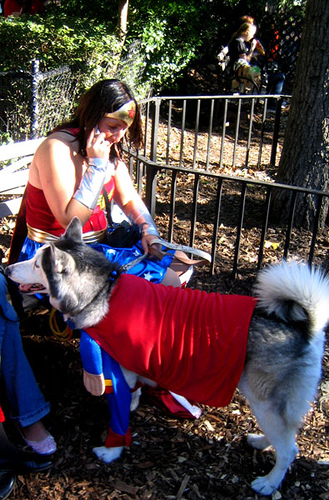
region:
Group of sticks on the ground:
[146, 445, 188, 476]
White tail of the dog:
[270, 268, 309, 294]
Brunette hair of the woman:
[95, 89, 110, 104]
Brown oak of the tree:
[281, 147, 326, 180]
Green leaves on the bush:
[143, 23, 167, 41]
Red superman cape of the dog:
[125, 308, 168, 337]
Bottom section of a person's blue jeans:
[19, 377, 34, 406]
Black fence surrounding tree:
[218, 175, 246, 276]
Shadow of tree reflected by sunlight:
[185, 202, 241, 225]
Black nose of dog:
[3, 266, 14, 276]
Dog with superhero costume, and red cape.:
[3, 217, 327, 498]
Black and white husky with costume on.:
[3, 214, 327, 497]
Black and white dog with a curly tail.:
[3, 213, 326, 498]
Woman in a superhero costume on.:
[5, 75, 204, 281]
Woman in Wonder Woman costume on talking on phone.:
[6, 74, 197, 288]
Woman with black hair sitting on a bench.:
[0, 75, 219, 285]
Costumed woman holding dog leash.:
[4, 73, 327, 493]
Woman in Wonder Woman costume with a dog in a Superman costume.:
[5, 78, 327, 495]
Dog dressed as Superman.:
[4, 213, 327, 497]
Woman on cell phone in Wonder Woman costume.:
[8, 73, 214, 286]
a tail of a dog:
[248, 258, 327, 337]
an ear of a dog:
[44, 238, 79, 280]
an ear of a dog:
[58, 214, 89, 245]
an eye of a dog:
[30, 255, 44, 274]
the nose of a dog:
[0, 264, 15, 280]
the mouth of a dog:
[11, 277, 47, 298]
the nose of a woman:
[108, 128, 123, 145]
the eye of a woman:
[105, 120, 118, 132]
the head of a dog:
[3, 212, 93, 315]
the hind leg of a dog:
[239, 359, 299, 494]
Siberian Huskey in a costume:
[2, 219, 314, 449]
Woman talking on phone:
[66, 75, 145, 165]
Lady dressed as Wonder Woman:
[11, 80, 167, 238]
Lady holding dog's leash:
[106, 234, 223, 285]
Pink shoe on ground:
[18, 423, 63, 456]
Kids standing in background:
[219, 12, 263, 71]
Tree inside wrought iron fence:
[276, 97, 328, 243]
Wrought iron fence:
[158, 89, 281, 180]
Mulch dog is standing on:
[191, 427, 316, 493]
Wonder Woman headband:
[102, 99, 137, 128]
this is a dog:
[109, 335, 225, 451]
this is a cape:
[154, 373, 220, 437]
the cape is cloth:
[180, 369, 208, 423]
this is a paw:
[249, 450, 296, 479]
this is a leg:
[255, 445, 285, 455]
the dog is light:
[210, 385, 289, 416]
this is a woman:
[30, 417, 35, 421]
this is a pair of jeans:
[23, 398, 53, 414]